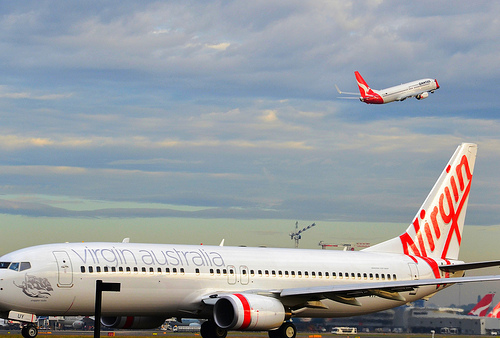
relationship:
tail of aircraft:
[349, 66, 378, 105] [334, 60, 446, 115]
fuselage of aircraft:
[382, 81, 433, 102] [334, 60, 446, 115]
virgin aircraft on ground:
[2, 141, 493, 334] [1, 325, 497, 336]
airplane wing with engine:
[204, 271, 499, 331] [212, 289, 287, 332]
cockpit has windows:
[3, 242, 74, 317] [1, 260, 34, 274]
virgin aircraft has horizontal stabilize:
[2, 141, 493, 334] [437, 254, 500, 276]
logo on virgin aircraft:
[12, 273, 57, 304] [2, 141, 493, 334]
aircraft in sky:
[334, 60, 446, 115] [3, 5, 497, 262]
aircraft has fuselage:
[334, 60, 446, 115] [382, 81, 433, 102]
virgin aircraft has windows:
[2, 141, 493, 334] [76, 261, 407, 288]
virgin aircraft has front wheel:
[2, 141, 493, 334] [24, 322, 43, 337]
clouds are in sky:
[9, 4, 496, 84] [3, 5, 497, 262]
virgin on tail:
[396, 151, 477, 283] [373, 128, 480, 283]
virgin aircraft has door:
[2, 141, 493, 334] [50, 247, 78, 291]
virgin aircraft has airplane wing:
[2, 141, 493, 334] [204, 271, 499, 331]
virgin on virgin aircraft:
[396, 151, 477, 283] [2, 141, 493, 334]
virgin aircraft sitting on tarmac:
[2, 141, 493, 334] [1, 325, 497, 336]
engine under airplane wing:
[212, 289, 287, 332] [204, 271, 499, 331]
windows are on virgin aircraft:
[76, 261, 407, 288] [2, 141, 493, 334]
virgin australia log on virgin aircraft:
[72, 240, 226, 271] [2, 141, 493, 334]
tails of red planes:
[469, 292, 500, 317] [422, 293, 499, 319]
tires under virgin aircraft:
[18, 324, 299, 335] [2, 141, 493, 334]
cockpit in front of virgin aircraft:
[3, 242, 74, 317] [2, 141, 493, 334]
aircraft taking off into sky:
[334, 60, 446, 115] [3, 5, 497, 262]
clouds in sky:
[9, 4, 496, 84] [3, 5, 497, 262]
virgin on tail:
[396, 151, 477, 283] [349, 66, 378, 105]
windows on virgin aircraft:
[76, 261, 407, 288] [2, 141, 493, 334]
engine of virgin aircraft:
[212, 289, 287, 332] [2, 141, 493, 334]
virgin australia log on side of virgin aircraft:
[72, 240, 226, 271] [2, 141, 493, 334]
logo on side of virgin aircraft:
[12, 273, 57, 304] [2, 141, 493, 334]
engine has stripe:
[212, 289, 287, 332] [232, 293, 251, 327]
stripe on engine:
[222, 287, 260, 328] [212, 289, 287, 332]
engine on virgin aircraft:
[212, 289, 287, 332] [0, 142, 500, 337]